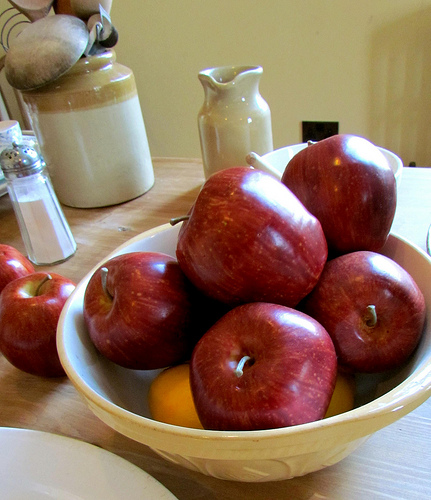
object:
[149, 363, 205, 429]
orange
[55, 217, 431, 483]
bowl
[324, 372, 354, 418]
orange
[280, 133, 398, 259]
apple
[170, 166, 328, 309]
apple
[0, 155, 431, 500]
table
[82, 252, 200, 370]
apple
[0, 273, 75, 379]
apple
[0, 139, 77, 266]
salt shaker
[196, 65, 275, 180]
pitcher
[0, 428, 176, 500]
plate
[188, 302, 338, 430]
apple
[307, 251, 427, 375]
apple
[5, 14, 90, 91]
ladle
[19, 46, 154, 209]
jar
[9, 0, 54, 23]
spoon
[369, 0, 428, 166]
shadow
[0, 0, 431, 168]
wall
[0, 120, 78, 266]
cap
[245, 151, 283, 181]
handle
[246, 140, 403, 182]
bowl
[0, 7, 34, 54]
whisk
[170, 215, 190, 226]
stem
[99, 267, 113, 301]
stem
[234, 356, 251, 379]
stem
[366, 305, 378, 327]
stem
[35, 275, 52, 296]
stem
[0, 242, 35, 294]
apple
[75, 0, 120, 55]
spoon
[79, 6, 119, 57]
utensil